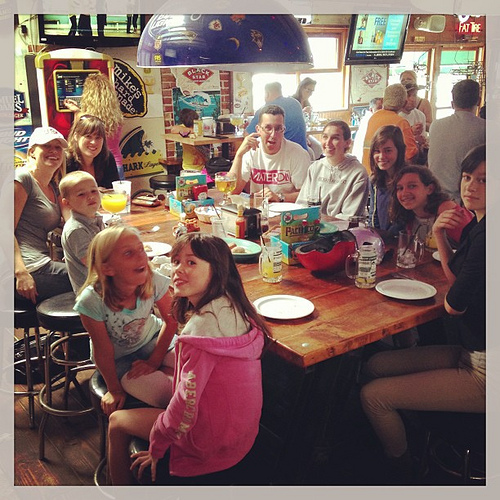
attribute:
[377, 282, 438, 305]
plate — empty, small, round, white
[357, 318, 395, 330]
table — wood, wooden, large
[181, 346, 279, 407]
jacket — pink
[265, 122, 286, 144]
glasses — dark framed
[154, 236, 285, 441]
girl — looking at camera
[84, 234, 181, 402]
girl — looking right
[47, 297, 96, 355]
barstool — black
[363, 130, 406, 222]
lady — looking at camera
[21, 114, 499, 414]
people — grouped, eating, smiling, drinking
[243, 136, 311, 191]
shirt — red, white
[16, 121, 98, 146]
baseball cap — white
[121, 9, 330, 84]
light — over table, blue, half domed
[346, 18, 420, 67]
tv — hanging, on wall, flat screen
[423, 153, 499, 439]
female — wearing black